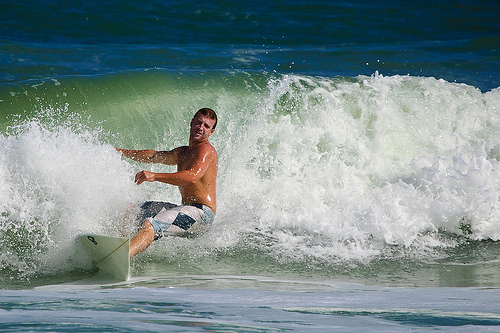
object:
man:
[78, 108, 217, 281]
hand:
[134, 170, 156, 185]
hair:
[194, 108, 218, 132]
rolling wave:
[0, 68, 497, 278]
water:
[0, 0, 500, 333]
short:
[139, 201, 215, 241]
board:
[81, 234, 130, 280]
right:
[437, 3, 495, 332]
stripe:
[97, 239, 129, 265]